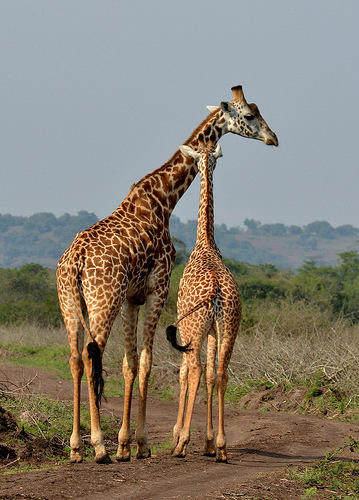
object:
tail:
[67, 254, 109, 416]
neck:
[196, 168, 214, 250]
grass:
[0, 391, 170, 474]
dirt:
[0, 363, 359, 500]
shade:
[187, 448, 359, 476]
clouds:
[177, 196, 198, 216]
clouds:
[21, 45, 148, 145]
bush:
[0, 261, 60, 328]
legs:
[115, 298, 140, 462]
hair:
[164, 324, 194, 355]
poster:
[0, 0, 359, 500]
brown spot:
[128, 202, 136, 215]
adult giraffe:
[55, 83, 280, 465]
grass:
[0, 313, 359, 424]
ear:
[179, 144, 200, 161]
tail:
[165, 273, 219, 355]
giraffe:
[165, 144, 243, 463]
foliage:
[298, 268, 302, 272]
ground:
[0, 321, 359, 500]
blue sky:
[0, 0, 359, 231]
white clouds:
[286, 109, 359, 169]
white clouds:
[250, 6, 314, 68]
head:
[177, 138, 225, 173]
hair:
[85, 340, 109, 413]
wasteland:
[0, 209, 359, 499]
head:
[205, 84, 280, 147]